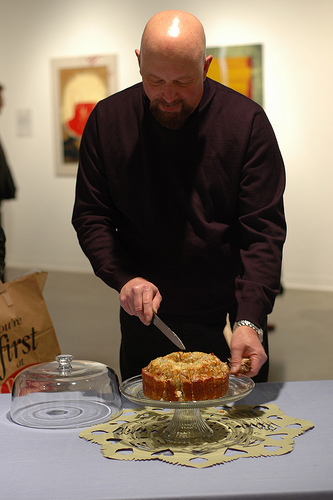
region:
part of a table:
[232, 402, 238, 412]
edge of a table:
[221, 484, 226, 491]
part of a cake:
[179, 365, 183, 374]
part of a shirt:
[216, 340, 224, 353]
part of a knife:
[165, 327, 166, 331]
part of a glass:
[79, 394, 94, 423]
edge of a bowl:
[63, 403, 71, 420]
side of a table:
[190, 465, 197, 488]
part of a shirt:
[196, 326, 206, 335]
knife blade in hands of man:
[141, 305, 189, 352]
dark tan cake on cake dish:
[136, 339, 231, 401]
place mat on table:
[80, 399, 316, 469]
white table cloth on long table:
[3, 371, 331, 498]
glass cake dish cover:
[6, 345, 124, 429]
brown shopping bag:
[0, 267, 65, 397]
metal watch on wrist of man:
[232, 319, 267, 344]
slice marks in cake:
[175, 362, 197, 400]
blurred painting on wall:
[40, 43, 124, 184]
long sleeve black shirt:
[68, 75, 303, 332]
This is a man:
[48, 5, 325, 470]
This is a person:
[64, 12, 308, 451]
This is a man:
[66, 7, 305, 461]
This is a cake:
[131, 333, 236, 447]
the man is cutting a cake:
[74, 8, 276, 443]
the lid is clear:
[3, 349, 121, 429]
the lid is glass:
[8, 352, 123, 433]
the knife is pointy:
[152, 318, 189, 351]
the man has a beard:
[154, 110, 184, 123]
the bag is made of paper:
[5, 236, 61, 351]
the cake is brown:
[138, 344, 229, 402]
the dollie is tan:
[215, 414, 317, 452]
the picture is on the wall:
[45, 54, 123, 88]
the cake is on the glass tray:
[116, 387, 254, 443]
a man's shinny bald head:
[137, 9, 207, 61]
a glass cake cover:
[7, 353, 122, 429]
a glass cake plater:
[118, 368, 255, 446]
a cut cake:
[140, 350, 231, 403]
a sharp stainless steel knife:
[151, 313, 186, 353]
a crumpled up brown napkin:
[229, 352, 251, 375]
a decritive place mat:
[79, 402, 315, 470]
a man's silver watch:
[230, 319, 264, 339]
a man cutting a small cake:
[69, 8, 295, 437]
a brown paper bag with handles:
[0, 263, 60, 393]